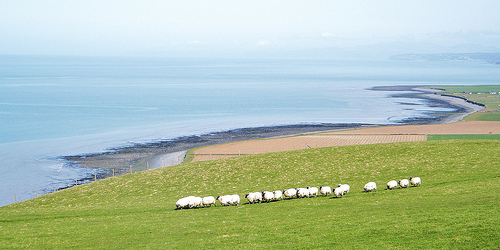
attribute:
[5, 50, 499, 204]
water — body, large, ocean water, blue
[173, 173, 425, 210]
sheep — grazing, walking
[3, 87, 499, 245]
field — grassy, farm field, green, large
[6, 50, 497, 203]
ocean — calm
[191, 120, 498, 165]
shore — ocean shore, beach side, sandy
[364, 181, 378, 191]
sheep — white, fluffy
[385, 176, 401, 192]
sheep — white, fluffy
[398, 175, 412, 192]
sheep — white, fluffy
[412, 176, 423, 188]
sheep — white, fluffy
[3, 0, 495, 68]
sky — cloudy, blue, white, here, clear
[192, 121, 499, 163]
strip — sand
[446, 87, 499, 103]
pool — small, water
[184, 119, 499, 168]
land — brown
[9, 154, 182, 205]
fence — wired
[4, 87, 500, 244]
landscape — large, grassy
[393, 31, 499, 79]
mountains — covered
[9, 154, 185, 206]
poles — wood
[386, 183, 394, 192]
head — black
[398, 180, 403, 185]
head — black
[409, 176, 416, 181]
head — black